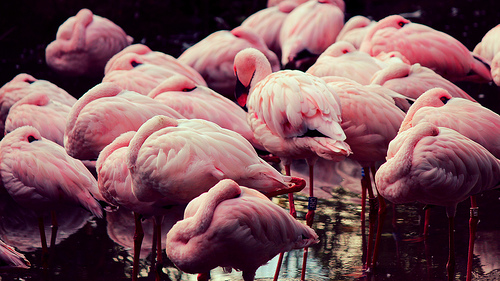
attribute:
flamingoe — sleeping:
[158, 177, 317, 278]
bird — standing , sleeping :
[236, 45, 345, 279]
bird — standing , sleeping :
[130, 106, 300, 280]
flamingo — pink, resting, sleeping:
[226, 45, 359, 169]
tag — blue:
[306, 196, 319, 213]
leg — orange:
[306, 165, 316, 223]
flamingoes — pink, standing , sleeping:
[3, 2, 495, 275]